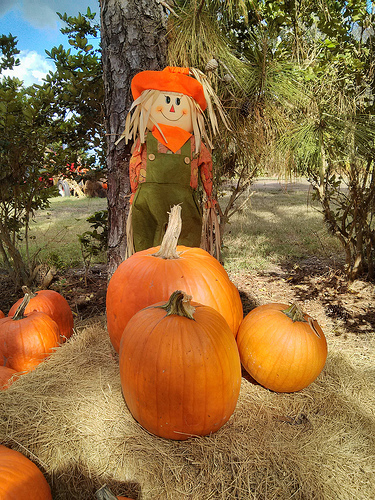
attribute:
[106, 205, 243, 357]
pumpkin — large, orange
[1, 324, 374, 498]
grass — brown, dry, large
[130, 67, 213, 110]
hat — orange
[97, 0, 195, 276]
bark — grey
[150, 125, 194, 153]
scarf — orange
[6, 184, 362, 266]
grass — short, dry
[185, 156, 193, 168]
button — brown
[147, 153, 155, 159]
button — brown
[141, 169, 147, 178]
button — brown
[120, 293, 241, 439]
pumpkin — orange, large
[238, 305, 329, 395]
pumpkin — orange, small, medium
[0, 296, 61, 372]
pumpkin — orange, small, medium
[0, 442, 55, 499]
pumpkin — orange, small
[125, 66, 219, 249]
scarecrow — smiling, decorative, standing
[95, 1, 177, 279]
tree — large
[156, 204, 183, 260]
stem — long, brown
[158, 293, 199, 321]
stem — short, brown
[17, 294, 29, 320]
stem — brown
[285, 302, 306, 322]
stem — brown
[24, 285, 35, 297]
stem — brown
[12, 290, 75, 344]
pumpkin — orange, small, on grass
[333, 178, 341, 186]
leaves — green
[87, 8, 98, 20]
leaves — green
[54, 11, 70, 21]
leaves — green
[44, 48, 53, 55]
leaves — green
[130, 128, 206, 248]
overall — green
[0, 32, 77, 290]
bush — large